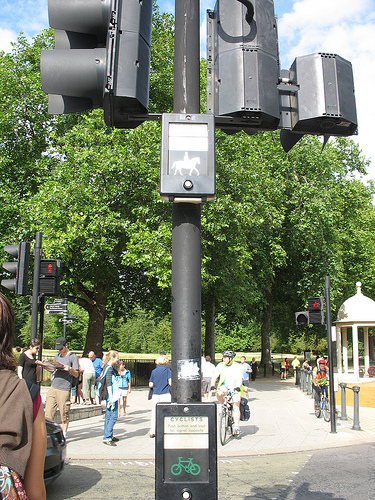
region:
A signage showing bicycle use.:
[155, 403, 217, 498]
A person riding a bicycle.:
[311, 356, 334, 427]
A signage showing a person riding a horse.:
[162, 112, 216, 200]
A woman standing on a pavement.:
[95, 349, 131, 447]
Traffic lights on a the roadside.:
[37, 0, 358, 137]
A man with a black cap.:
[45, 336, 86, 435]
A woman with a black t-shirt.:
[16, 333, 42, 390]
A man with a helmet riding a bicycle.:
[214, 349, 249, 447]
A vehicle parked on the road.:
[44, 418, 69, 488]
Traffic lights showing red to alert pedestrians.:
[1, 230, 67, 338]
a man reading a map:
[36, 336, 82, 439]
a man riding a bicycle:
[206, 348, 249, 448]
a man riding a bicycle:
[305, 352, 332, 422]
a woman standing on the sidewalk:
[96, 348, 124, 453]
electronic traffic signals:
[38, 0, 355, 155]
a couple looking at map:
[14, 336, 81, 446]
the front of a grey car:
[41, 418, 72, 488]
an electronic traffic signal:
[291, 274, 342, 436]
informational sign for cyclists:
[159, 411, 211, 488]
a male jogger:
[238, 353, 252, 395]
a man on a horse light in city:
[154, 94, 222, 214]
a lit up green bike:
[156, 451, 213, 483]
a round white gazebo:
[327, 268, 372, 418]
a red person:
[41, 252, 56, 286]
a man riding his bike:
[210, 335, 258, 445]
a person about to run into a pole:
[306, 344, 348, 431]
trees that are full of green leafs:
[10, 103, 370, 387]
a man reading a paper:
[33, 339, 83, 432]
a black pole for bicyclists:
[289, 267, 345, 433]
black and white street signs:
[43, 294, 79, 335]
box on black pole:
[146, 104, 229, 220]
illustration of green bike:
[166, 453, 202, 479]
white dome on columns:
[334, 282, 370, 348]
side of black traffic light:
[36, 3, 153, 133]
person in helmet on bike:
[206, 343, 254, 430]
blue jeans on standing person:
[96, 397, 125, 451]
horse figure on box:
[164, 147, 204, 183]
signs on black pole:
[41, 290, 73, 322]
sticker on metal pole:
[171, 351, 206, 385]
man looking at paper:
[34, 331, 87, 401]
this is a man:
[221, 351, 241, 393]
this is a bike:
[217, 396, 236, 438]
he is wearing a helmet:
[220, 349, 235, 358]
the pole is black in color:
[181, 332, 195, 350]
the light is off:
[297, 312, 312, 324]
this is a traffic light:
[20, 6, 348, 174]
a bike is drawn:
[169, 455, 202, 478]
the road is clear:
[302, 451, 353, 485]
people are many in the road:
[23, 364, 125, 465]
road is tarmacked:
[329, 462, 364, 494]